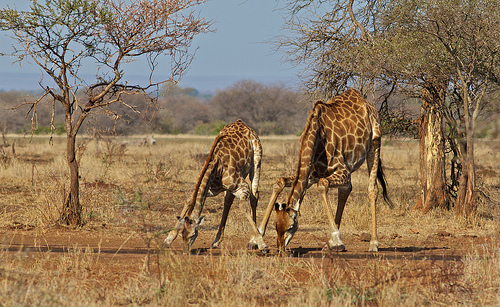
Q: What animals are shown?
A: Giraffes.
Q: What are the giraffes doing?
A: Eating.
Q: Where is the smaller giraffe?
A: Left of larger giraffe.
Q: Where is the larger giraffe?
A: Right of smaller giraffe.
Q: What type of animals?
A: Giraffes.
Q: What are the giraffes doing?
A: Grazing.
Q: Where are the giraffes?
A: On the dirt.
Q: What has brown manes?
A: The giraffes.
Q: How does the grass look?
A: Dead.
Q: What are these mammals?
A: Giraffes.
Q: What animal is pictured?
A: Giraffes.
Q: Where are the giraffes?
A: In a field.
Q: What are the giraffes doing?
A: Drinking.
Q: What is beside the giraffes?
A: Trees.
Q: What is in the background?
A: Trees.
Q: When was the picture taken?
A: During day hours.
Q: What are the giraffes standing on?
A: Dirt.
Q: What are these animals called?
A: Giraffes.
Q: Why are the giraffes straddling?
A: It is hard for them to get to the grass, with their long legs and necks.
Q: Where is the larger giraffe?
A: To the right of the smaller one.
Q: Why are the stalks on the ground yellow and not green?
A: They are dried out, from lack of rain.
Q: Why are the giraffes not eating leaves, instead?
A: The trees are bare.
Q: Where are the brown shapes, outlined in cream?
A: On the giraffes.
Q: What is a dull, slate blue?
A: The sky.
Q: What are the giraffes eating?
A: Grass.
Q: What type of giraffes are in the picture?
A: Rothschild giraffes.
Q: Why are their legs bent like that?
A: Too tall.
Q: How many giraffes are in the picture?
A: Two.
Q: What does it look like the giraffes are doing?
A: Dancing.